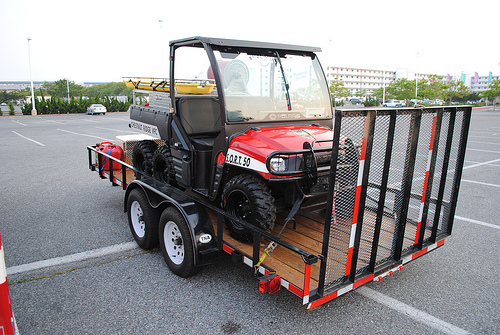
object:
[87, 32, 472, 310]
trailer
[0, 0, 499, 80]
sky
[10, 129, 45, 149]
line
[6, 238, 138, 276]
line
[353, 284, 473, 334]
line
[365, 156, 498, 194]
line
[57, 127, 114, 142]
line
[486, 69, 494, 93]
flag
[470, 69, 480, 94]
flag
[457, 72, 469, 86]
flag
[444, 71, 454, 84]
flag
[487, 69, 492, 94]
pole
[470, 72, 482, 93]
pole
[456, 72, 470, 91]
pole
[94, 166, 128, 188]
hazard tape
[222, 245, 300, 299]
hazard tape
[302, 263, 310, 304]
hazard tape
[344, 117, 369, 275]
hazard tape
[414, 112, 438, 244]
hazard tape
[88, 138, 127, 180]
gas can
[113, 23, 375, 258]
vehicle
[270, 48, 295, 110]
wiper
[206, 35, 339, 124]
windshield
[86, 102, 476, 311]
small brown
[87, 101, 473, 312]
black trailer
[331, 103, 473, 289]
empty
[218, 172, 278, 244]
black tire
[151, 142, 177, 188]
black tire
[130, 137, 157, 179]
black tire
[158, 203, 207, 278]
black tire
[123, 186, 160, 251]
black tire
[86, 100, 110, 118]
vehicle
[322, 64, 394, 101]
building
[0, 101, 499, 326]
parking lot